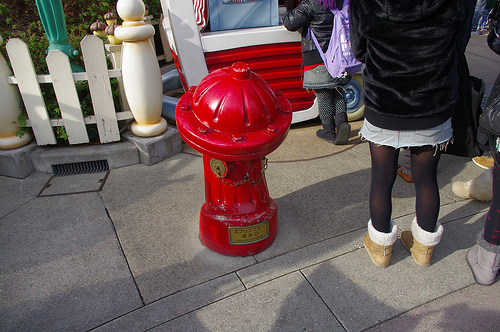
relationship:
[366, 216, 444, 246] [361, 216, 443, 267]
fleece lining inside of boots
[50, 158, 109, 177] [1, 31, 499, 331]
grate on curb of sidewalk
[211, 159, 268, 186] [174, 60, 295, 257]
chain hanging from fire hydrant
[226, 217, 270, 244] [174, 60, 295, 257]
plate on front of fire hydrant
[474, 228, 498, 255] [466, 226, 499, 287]
fleece lining inside boot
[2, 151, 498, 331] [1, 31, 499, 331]
shadows cast on sidewalk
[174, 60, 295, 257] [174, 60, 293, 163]
fire hydrant has top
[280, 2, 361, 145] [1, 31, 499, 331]
girl standing on sidewalk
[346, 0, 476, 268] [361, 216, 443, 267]
woman wearing boots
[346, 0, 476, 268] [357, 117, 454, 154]
woman wearing skirt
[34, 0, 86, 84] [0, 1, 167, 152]
pole inside fence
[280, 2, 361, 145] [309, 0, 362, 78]
girl wearing backpack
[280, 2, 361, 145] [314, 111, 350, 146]
girl wearing uggs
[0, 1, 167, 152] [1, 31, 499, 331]
fence next to sidewalk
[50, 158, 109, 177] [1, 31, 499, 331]
grate on side of sidewalk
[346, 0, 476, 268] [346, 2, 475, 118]
woman wearing jacket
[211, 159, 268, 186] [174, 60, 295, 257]
chain hanging on fire hydrant